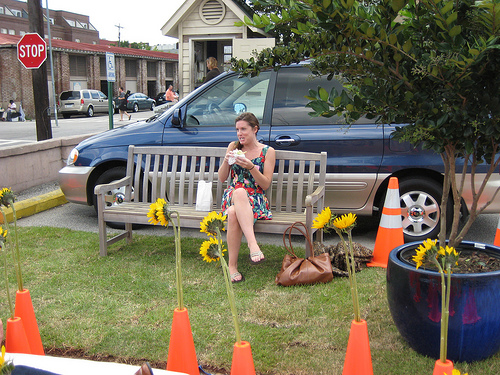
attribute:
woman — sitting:
[218, 109, 275, 282]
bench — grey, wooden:
[94, 145, 333, 257]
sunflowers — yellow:
[157, 204, 366, 252]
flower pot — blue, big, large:
[386, 240, 500, 360]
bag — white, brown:
[194, 180, 218, 212]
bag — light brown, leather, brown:
[277, 226, 332, 290]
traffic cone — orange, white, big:
[165, 308, 200, 374]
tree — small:
[280, 0, 499, 248]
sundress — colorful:
[228, 165, 267, 215]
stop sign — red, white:
[17, 34, 47, 69]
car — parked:
[117, 93, 158, 109]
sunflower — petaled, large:
[336, 210, 367, 328]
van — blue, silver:
[69, 66, 500, 177]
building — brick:
[8, 28, 167, 85]